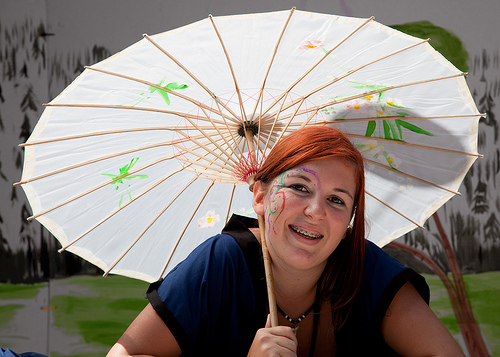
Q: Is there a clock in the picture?
A: No, there are no clocks.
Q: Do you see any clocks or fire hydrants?
A: No, there are no clocks or fire hydrants.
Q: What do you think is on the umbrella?
A: The flowers are on the umbrella.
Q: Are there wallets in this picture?
A: No, there are no wallets.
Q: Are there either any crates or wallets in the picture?
A: No, there are no wallets or crates.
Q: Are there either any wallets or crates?
A: No, there are no wallets or crates.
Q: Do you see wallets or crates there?
A: No, there are no wallets or crates.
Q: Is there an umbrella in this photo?
A: Yes, there is an umbrella.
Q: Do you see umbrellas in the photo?
A: Yes, there is an umbrella.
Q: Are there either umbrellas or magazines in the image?
A: Yes, there is an umbrella.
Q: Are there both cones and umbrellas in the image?
A: No, there is an umbrella but no cones.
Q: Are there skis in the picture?
A: No, there are no skis.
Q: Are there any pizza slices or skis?
A: No, there are no skis or pizza slices.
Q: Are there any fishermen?
A: No, there are no fishermen.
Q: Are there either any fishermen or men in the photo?
A: No, there are no fishermen or men.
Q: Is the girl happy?
A: Yes, the girl is happy.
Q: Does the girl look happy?
A: Yes, the girl is happy.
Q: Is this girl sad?
A: No, the girl is happy.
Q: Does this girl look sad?
A: No, the girl is happy.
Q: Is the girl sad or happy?
A: The girl is happy.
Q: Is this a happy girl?
A: Yes, this is a happy girl.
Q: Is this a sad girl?
A: No, this is a happy girl.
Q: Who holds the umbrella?
A: The girl holds the umbrella.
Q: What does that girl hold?
A: The girl holds the umbrella.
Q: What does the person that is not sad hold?
A: The girl holds the umbrella.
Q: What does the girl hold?
A: The girl holds the umbrella.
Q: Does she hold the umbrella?
A: Yes, the girl holds the umbrella.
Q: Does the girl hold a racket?
A: No, the girl holds the umbrella.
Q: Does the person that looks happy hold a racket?
A: No, the girl holds the umbrella.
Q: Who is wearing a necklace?
A: The girl is wearing a necklace.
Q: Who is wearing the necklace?
A: The girl is wearing a necklace.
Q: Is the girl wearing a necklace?
A: Yes, the girl is wearing a necklace.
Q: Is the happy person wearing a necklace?
A: Yes, the girl is wearing a necklace.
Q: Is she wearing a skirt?
A: No, the girl is wearing a necklace.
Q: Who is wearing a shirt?
A: The girl is wearing a shirt.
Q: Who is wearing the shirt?
A: The girl is wearing a shirt.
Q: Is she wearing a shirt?
A: Yes, the girl is wearing a shirt.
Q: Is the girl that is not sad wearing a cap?
A: No, the girl is wearing a shirt.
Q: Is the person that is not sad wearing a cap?
A: No, the girl is wearing a shirt.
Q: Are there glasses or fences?
A: No, there are no fences or glasses.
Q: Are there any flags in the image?
A: No, there are no flags.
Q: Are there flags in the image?
A: No, there are no flags.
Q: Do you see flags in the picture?
A: No, there are no flags.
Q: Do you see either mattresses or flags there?
A: No, there are no flags or mattresses.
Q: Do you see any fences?
A: No, there are no fences.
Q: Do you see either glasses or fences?
A: No, there are no fences or glasses.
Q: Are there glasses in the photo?
A: No, there are no glasses.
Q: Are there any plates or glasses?
A: No, there are no glasses or plates.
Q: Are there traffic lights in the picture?
A: No, there are no traffic lights.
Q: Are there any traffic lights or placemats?
A: No, there are no traffic lights or placemats.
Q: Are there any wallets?
A: No, there are no wallets.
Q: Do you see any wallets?
A: No, there are no wallets.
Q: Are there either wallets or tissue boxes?
A: No, there are no wallets or tissue boxes.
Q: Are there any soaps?
A: No, there are no soaps.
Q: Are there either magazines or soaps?
A: No, there are no soaps or magazines.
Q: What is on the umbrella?
A: The flowers are on the umbrella.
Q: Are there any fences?
A: No, there are no fences.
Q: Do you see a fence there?
A: No, there are no fences.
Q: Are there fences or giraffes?
A: No, there are no fences or giraffes.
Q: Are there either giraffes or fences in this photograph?
A: No, there are no fences or giraffes.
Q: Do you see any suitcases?
A: No, there are no suitcases.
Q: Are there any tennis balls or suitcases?
A: No, there are no suitcases or tennis balls.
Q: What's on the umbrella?
A: The flowers are on the umbrella.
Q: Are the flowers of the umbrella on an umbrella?
A: Yes, the flowers are on an umbrella.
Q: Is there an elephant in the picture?
A: No, there are no elephants.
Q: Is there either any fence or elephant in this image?
A: No, there are no elephants or fences.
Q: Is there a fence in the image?
A: No, there are no fences.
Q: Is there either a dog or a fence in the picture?
A: No, there are no fences or dogs.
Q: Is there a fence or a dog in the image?
A: No, there are no fences or dogs.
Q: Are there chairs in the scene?
A: No, there are no chairs.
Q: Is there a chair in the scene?
A: No, there are no chairs.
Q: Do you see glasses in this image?
A: No, there are no glasses.